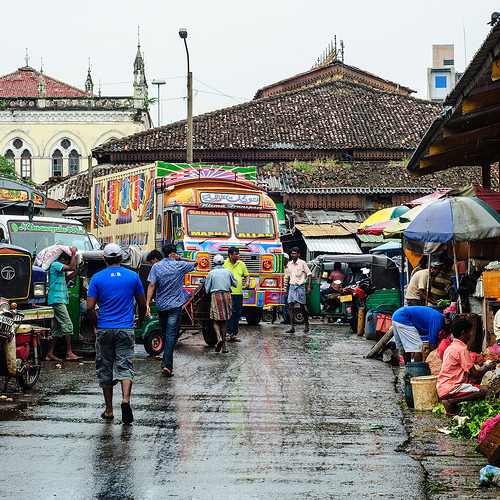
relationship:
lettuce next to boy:
[463, 392, 482, 407] [435, 318, 492, 414]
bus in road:
[88, 162, 288, 324] [156, 308, 356, 494]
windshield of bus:
[181, 217, 295, 240] [88, 162, 288, 324]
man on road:
[90, 241, 146, 422] [156, 308, 356, 494]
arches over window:
[1, 122, 139, 163] [38, 154, 90, 179]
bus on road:
[88, 162, 288, 324] [156, 308, 356, 494]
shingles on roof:
[305, 100, 378, 139] [0, 61, 129, 111]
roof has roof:
[0, 61, 129, 111] [0, 64, 96, 96]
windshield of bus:
[181, 217, 295, 240] [86, 134, 319, 327]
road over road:
[156, 308, 356, 494] [156, 308, 356, 494]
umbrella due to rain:
[368, 144, 485, 162] [276, 358, 339, 405]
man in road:
[90, 241, 146, 422] [156, 308, 356, 494]